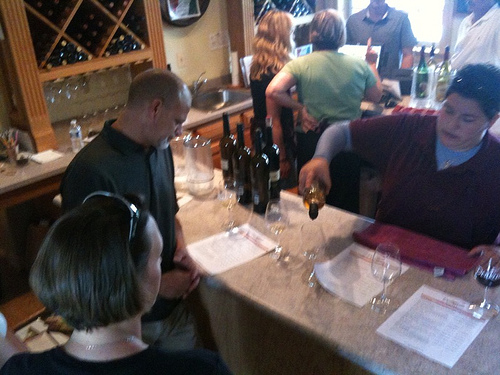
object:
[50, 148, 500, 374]
counter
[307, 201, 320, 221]
tip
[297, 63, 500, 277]
man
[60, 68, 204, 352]
man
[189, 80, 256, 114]
sink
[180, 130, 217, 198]
container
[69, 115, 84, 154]
bottle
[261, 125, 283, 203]
botles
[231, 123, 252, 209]
botles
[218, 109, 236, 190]
botles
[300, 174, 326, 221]
botles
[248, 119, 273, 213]
bottle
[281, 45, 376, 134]
green shirt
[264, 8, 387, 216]
woman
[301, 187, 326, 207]
wine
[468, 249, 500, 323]
glass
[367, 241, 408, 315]
glass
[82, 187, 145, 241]
glasses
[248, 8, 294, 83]
blonde hair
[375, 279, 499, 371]
paper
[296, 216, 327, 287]
glass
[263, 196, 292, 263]
glass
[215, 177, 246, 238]
glass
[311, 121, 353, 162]
undershirt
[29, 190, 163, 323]
woman's head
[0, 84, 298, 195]
counter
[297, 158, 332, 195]
hand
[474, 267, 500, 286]
wine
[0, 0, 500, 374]
bar